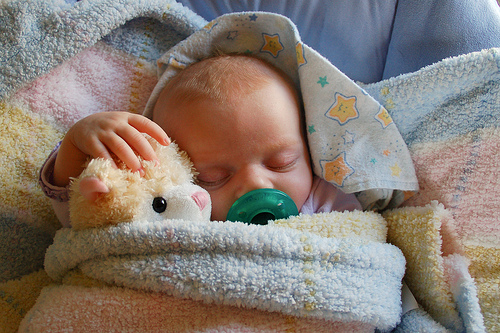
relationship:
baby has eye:
[20, 56, 407, 333] [267, 151, 297, 174]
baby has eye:
[20, 56, 407, 333] [194, 167, 229, 184]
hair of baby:
[163, 52, 280, 107] [52, 50, 313, 230]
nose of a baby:
[232, 161, 274, 203] [36, 50, 366, 266]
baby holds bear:
[20, 56, 407, 333] [65, 133, 211, 227]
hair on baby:
[163, 42, 280, 107] [53, 62, 423, 290]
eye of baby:
[198, 162, 233, 185] [20, 56, 407, 333]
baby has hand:
[20, 56, 407, 333] [76, 106, 171, 174]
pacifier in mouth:
[226, 189, 299, 224] [221, 190, 298, 222]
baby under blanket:
[20, 56, 407, 333] [143, 9, 426, 198]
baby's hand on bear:
[52, 109, 172, 181] [65, 133, 211, 227]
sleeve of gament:
[42, 145, 78, 230] [32, 166, 373, 232]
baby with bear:
[57, 53, 360, 215] [65, 134, 209, 228]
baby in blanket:
[57, 53, 360, 215] [19, 197, 485, 331]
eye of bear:
[149, 195, 169, 213] [65, 133, 211, 227]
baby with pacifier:
[20, 56, 407, 333] [235, 192, 292, 223]